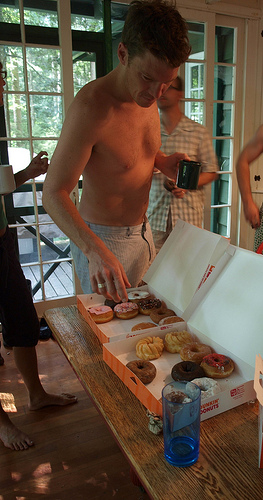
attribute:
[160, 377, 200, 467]
cup — blue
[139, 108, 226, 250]
shirt — beige, plaid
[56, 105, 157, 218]
man — shirtless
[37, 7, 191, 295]
man — shirtless, having breakfast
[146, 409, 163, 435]
napkin — crumpled up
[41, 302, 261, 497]
table — wood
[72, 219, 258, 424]
donuts — tasty, Dunkin Donuts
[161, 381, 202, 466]
glass — clear, blue, drinking glass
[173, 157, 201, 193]
glass — blue, drink glass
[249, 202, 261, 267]
shorts — light , colored, striped, Bermuda style, man's shorts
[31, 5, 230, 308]
man — wearing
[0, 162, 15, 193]
coffee cup — white, glass, coffee cup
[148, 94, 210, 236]
man — wearing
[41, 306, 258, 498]
wood table — brown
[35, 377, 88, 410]
feet — shoeless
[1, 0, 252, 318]
doors — white, french style, wood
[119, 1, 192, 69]
hair — short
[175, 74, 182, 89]
hair — short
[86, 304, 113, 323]
donut — strawberry, iced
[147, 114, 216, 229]
shirt — beige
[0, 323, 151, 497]
floor — brown, hardwood, dusty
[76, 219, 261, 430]
boxes — two boxes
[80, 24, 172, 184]
man — shirtless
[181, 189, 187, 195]
ring — gold, man's ring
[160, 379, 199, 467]
glass — empty, blue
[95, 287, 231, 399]
donuts — varied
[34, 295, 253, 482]
table — wooden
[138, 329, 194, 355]
doughnut — powdered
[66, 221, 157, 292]
pants — gray